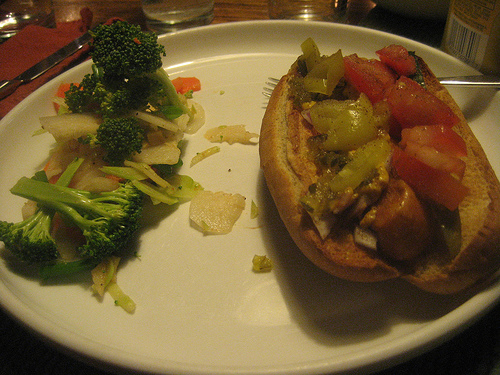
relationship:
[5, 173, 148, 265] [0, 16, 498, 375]
broccoli on top of plate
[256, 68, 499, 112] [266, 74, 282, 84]
fork has tine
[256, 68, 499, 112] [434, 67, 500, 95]
fork has handle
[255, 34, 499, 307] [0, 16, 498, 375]
sandwich on top of plate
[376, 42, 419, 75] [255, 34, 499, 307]
tomato on top of sandwich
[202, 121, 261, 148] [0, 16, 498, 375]
food on top of plate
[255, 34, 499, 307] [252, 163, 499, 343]
sandwich has shadow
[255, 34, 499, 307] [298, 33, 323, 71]
sandwich contains pepper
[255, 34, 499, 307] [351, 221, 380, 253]
sandwich contains onion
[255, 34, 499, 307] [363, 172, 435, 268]
sandwich contains sausage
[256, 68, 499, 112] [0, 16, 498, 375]
fork on top of plate